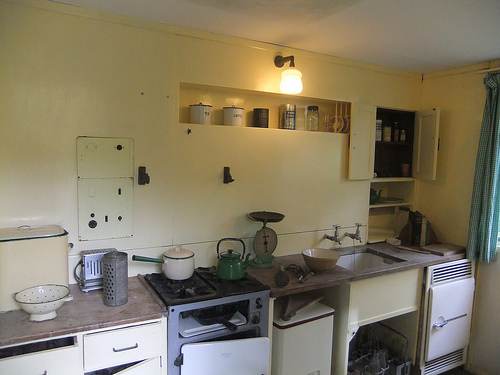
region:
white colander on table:
[9, 280, 97, 342]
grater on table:
[92, 246, 146, 331]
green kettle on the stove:
[198, 228, 287, 301]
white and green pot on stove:
[128, 229, 240, 304]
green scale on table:
[240, 178, 311, 285]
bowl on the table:
[300, 240, 344, 275]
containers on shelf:
[188, 85, 361, 145]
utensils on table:
[268, 252, 324, 294]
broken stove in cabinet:
[138, 264, 295, 374]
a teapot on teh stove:
[183, 215, 325, 315]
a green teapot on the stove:
[205, 221, 260, 312]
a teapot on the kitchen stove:
[190, 207, 262, 315]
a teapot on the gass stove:
[217, 232, 292, 319]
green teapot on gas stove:
[164, 216, 249, 320]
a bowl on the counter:
[302, 229, 337, 269]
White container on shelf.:
[183, 97, 216, 129]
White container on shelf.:
[219, 102, 254, 142]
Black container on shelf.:
[249, 105, 276, 131]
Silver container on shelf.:
[276, 100, 311, 147]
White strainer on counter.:
[16, 287, 55, 303]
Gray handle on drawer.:
[108, 338, 165, 356]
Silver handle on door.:
[436, 310, 471, 319]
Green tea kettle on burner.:
[213, 250, 270, 282]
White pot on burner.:
[153, 245, 203, 275]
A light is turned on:
[273, 63, 304, 96]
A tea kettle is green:
[210, 230, 251, 280]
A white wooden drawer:
[75, 312, 170, 372]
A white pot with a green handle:
[125, 236, 197, 281]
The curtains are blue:
[460, 65, 495, 265]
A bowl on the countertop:
[297, 237, 343, 282]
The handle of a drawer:
[105, 336, 141, 356]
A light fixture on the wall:
[265, 45, 305, 100]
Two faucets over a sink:
[320, 218, 405, 276]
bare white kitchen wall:
[5, 3, 368, 253]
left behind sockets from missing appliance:
[75, 135, 148, 236]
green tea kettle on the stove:
[211, 235, 256, 281]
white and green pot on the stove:
[132, 240, 198, 285]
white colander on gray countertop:
[12, 282, 69, 322]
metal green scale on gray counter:
[245, 197, 286, 268]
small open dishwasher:
[345, 306, 420, 372]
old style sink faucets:
[320, 216, 370, 247]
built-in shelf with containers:
[177, 77, 350, 137]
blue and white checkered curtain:
[464, 72, 498, 264]